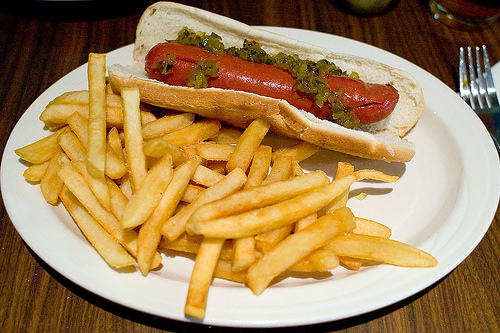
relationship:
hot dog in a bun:
[142, 33, 409, 124] [98, 1, 427, 169]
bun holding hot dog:
[98, 1, 427, 169] [142, 33, 409, 124]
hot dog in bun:
[142, 33, 409, 124] [98, 1, 427, 169]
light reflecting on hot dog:
[227, 65, 361, 102] [142, 33, 409, 124]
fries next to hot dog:
[19, 98, 436, 320] [142, 33, 409, 124]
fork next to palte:
[454, 38, 500, 117] [6, 19, 499, 333]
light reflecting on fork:
[460, 76, 495, 96] [454, 38, 500, 117]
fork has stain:
[454, 38, 500, 117] [461, 73, 468, 88]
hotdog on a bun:
[142, 33, 409, 124] [98, 1, 427, 169]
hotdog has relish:
[142, 33, 409, 124] [158, 23, 369, 123]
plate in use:
[6, 19, 499, 333] [16, 2, 443, 297]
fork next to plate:
[454, 38, 500, 117] [6, 19, 499, 333]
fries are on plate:
[19, 98, 436, 320] [6, 19, 499, 333]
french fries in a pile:
[23, 73, 428, 306] [19, 98, 436, 320]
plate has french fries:
[6, 19, 499, 333] [23, 73, 428, 306]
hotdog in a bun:
[142, 33, 409, 124] [98, 1, 427, 169]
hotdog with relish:
[142, 33, 409, 124] [158, 23, 369, 123]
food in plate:
[16, 2, 443, 297] [6, 19, 499, 333]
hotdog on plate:
[142, 33, 409, 124] [6, 19, 499, 333]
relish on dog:
[142, 33, 409, 124] [102, 8, 439, 175]